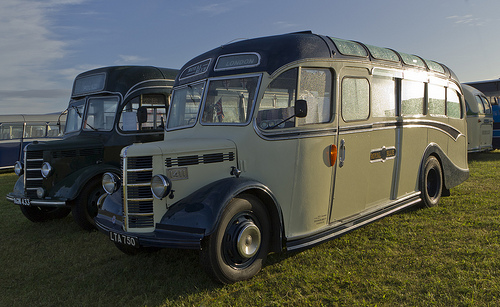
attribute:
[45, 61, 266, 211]
car — black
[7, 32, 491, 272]
vehicles — old fashioned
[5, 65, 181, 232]
car — black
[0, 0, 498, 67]
sky — shining, bright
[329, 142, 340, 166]
light — orange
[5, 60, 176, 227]
bus — black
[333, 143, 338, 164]
light — red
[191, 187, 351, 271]
wheels — black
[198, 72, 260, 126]
window — small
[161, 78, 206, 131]
window — small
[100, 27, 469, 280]
car — beige, olive green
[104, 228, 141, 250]
license plate — white, black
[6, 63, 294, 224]
bus — dark green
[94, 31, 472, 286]
vehicles — large, parked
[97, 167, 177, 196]
car lights — round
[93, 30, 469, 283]
vehicle — vintage, retro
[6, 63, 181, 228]
vehicle — retro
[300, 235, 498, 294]
field — grassy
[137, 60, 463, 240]
vehicle — vintage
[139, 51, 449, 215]
vehicle — vintage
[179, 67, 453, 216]
bus — light green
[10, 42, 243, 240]
car — black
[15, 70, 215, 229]
car — black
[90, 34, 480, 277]
bus — light green